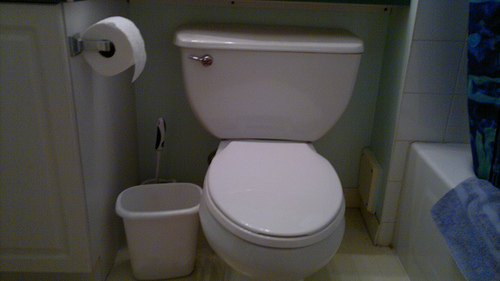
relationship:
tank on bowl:
[182, 42, 355, 138] [173, 17, 383, 277]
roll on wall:
[80, 17, 146, 75] [48, 3, 94, 113]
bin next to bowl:
[109, 179, 220, 279] [173, 17, 383, 277]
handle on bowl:
[187, 49, 218, 68] [173, 17, 383, 277]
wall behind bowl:
[196, 7, 347, 23] [173, 17, 383, 277]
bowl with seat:
[173, 17, 383, 277] [202, 138, 343, 247]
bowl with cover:
[173, 17, 383, 277] [207, 134, 341, 251]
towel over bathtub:
[433, 180, 498, 274] [400, 140, 497, 246]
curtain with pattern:
[460, 7, 493, 195] [468, 73, 498, 104]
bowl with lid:
[173, 17, 383, 277] [205, 136, 345, 243]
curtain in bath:
[460, 7, 493, 195] [395, 135, 494, 278]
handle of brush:
[147, 113, 170, 178] [149, 114, 181, 188]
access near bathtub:
[357, 152, 383, 228] [391, 138, 490, 278]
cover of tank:
[170, 24, 369, 61] [182, 42, 355, 138]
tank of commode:
[182, 42, 355, 138] [167, 26, 372, 270]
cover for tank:
[170, 24, 369, 61] [182, 42, 355, 138]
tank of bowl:
[182, 42, 355, 138] [200, 138, 354, 278]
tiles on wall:
[364, 6, 480, 246] [380, 5, 481, 266]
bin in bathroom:
[109, 179, 220, 279] [2, 2, 484, 279]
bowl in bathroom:
[173, 17, 383, 277] [2, 2, 484, 279]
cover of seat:
[207, 134, 341, 251] [204, 134, 354, 239]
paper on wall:
[83, 14, 145, 77] [32, 11, 153, 152]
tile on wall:
[397, 85, 467, 141] [404, 16, 498, 141]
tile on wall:
[379, 178, 399, 218] [377, 65, 407, 235]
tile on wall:
[377, 205, 395, 237] [355, 129, 407, 249]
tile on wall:
[408, 40, 466, 98] [399, 4, 469, 142]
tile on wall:
[413, 7, 493, 45] [410, 7, 473, 145]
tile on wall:
[452, 47, 492, 101] [406, 11, 493, 143]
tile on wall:
[433, 89, 473, 145] [406, 7, 486, 145]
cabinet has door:
[8, 7, 138, 261] [6, 9, 93, 279]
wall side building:
[66, 74, 142, 175] [8, 13, 486, 280]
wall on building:
[22, 107, 127, 188] [50, 101, 123, 181]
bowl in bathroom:
[173, 17, 383, 277] [105, 9, 406, 263]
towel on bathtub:
[433, 180, 498, 247] [410, 141, 499, 269]